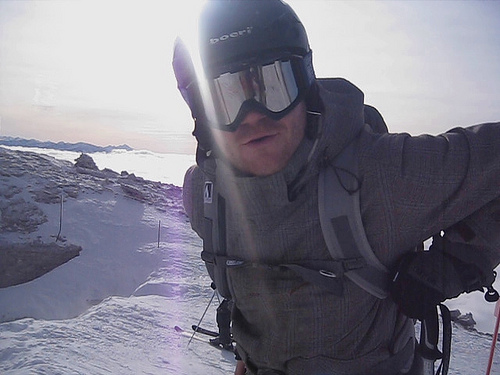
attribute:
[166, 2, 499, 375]
man — sporting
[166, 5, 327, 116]
helmet — black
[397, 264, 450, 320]
gloves — black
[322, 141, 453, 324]
backpack — gray, black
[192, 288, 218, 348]
ski pole — red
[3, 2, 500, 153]
sky — light blue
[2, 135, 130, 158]
mountains — distant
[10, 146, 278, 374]
snow — white